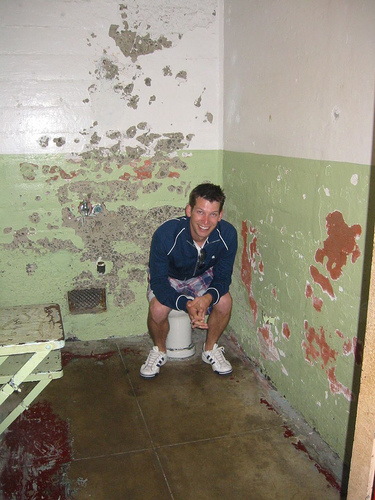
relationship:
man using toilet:
[136, 174, 245, 396] [154, 299, 200, 365]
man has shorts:
[136, 174, 245, 396] [148, 278, 225, 302]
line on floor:
[132, 384, 162, 454] [19, 360, 347, 499]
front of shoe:
[140, 362, 154, 376] [137, 342, 169, 379]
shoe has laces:
[137, 342, 169, 379] [149, 350, 161, 368]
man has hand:
[136, 174, 245, 396] [185, 292, 213, 332]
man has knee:
[136, 174, 245, 396] [143, 306, 169, 327]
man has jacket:
[136, 174, 245, 396] [151, 218, 242, 308]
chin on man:
[198, 231, 211, 238] [136, 174, 245, 396]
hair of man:
[197, 184, 221, 202] [136, 174, 245, 396]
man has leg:
[136, 174, 245, 396] [200, 293, 233, 363]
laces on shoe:
[149, 350, 161, 368] [137, 342, 169, 379]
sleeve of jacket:
[145, 243, 185, 309] [151, 218, 242, 308]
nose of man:
[201, 214, 210, 226] [136, 174, 245, 396]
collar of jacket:
[184, 219, 194, 245] [151, 218, 242, 308]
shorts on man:
[148, 278, 225, 302] [136, 174, 245, 396]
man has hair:
[136, 174, 245, 396] [197, 184, 221, 202]